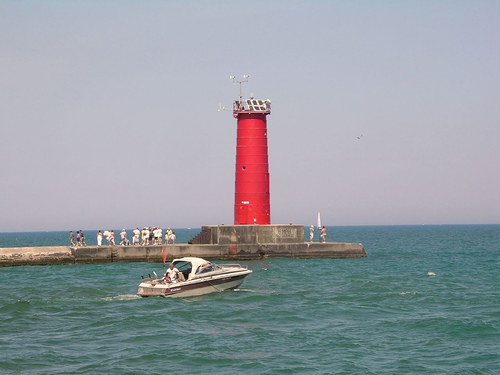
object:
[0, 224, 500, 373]
water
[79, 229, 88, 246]
people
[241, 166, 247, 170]
circle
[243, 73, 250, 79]
light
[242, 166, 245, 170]
hole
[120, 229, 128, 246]
people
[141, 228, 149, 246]
people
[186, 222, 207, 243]
stair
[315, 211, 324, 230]
boat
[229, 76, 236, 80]
lamps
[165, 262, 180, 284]
person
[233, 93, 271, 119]
structure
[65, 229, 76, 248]
people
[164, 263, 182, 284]
couple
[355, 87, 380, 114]
ground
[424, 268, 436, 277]
buoy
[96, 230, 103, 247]
people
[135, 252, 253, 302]
boat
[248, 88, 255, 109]
person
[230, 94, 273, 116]
deck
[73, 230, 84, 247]
people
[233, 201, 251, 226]
door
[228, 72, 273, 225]
lighthouse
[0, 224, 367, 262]
dock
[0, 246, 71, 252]
path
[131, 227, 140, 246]
people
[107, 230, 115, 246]
people